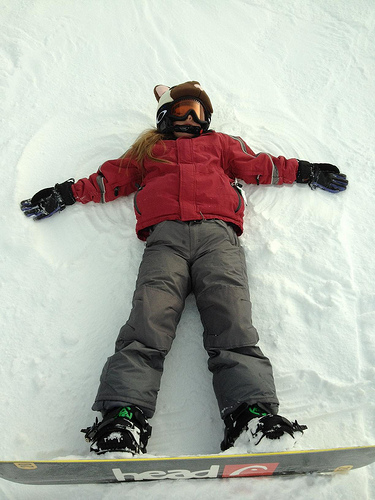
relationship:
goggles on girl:
[170, 98, 209, 121] [20, 83, 347, 453]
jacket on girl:
[71, 131, 299, 244] [20, 83, 347, 453]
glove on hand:
[300, 160, 350, 191] [20, 174, 72, 236]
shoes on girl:
[90, 403, 294, 451] [20, 83, 347, 453]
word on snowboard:
[113, 462, 221, 488] [0, 443, 372, 485]